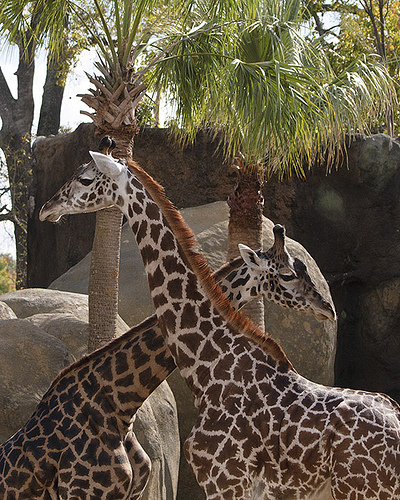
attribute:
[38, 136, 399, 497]
giraffe — brown, white, bending forward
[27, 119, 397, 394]
boulders — gray, here, smooth, enclosure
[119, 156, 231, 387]
long neck — thin, tall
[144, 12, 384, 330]
tree — palm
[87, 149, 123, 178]
left ear — tan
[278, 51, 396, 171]
leaves — turning brown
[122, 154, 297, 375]
mane — reddish brown, orange, brown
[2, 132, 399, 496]
giraffes — together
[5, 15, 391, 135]
sky — pale blue